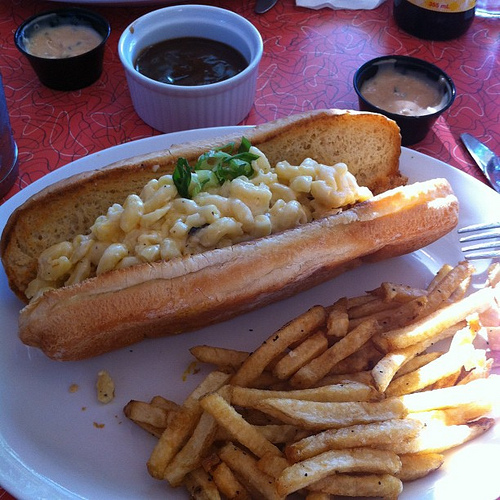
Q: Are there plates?
A: Yes, there is a plate.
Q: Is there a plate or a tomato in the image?
A: Yes, there is a plate.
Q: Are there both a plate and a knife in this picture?
A: Yes, there are both a plate and a knife.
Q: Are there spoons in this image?
A: No, there are no spoons.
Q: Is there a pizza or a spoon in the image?
A: No, there are no spoons or pizzas.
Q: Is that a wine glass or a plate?
A: That is a plate.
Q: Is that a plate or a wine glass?
A: That is a plate.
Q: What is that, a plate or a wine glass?
A: That is a plate.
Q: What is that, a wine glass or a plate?
A: That is a plate.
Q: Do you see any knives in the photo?
A: Yes, there is a knife.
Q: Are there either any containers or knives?
A: Yes, there is a knife.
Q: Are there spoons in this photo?
A: No, there are no spoons.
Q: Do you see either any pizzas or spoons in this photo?
A: No, there are no spoons or pizzas.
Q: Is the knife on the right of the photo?
A: Yes, the knife is on the right of the image.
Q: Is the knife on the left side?
A: No, the knife is on the right of the image.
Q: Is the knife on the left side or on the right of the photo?
A: The knife is on the right of the image.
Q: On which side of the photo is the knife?
A: The knife is on the right of the image.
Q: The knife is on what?
A: The knife is on the table.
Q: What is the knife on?
A: The knife is on the table.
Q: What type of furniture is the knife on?
A: The knife is on the table.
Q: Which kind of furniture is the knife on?
A: The knife is on the table.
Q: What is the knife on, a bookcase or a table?
A: The knife is on a table.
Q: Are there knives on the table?
A: Yes, there is a knife on the table.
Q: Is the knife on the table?
A: Yes, the knife is on the table.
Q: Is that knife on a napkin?
A: No, the knife is on the table.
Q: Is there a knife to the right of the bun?
A: Yes, there is a knife to the right of the bun.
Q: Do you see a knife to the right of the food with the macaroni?
A: Yes, there is a knife to the right of the bun.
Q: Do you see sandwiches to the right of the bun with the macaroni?
A: No, there is a knife to the right of the bun.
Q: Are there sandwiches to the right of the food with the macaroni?
A: No, there is a knife to the right of the bun.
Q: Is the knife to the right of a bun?
A: Yes, the knife is to the right of a bun.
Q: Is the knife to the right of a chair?
A: No, the knife is to the right of a bun.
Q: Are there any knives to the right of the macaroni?
A: Yes, there is a knife to the right of the macaroni.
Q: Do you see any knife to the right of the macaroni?
A: Yes, there is a knife to the right of the macaroni.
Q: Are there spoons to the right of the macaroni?
A: No, there is a knife to the right of the macaroni.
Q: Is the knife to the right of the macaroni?
A: Yes, the knife is to the right of the macaroni.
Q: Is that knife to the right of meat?
A: No, the knife is to the right of the macaroni.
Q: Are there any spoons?
A: No, there are no spoons.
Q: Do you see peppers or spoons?
A: No, there are no spoons or peppers.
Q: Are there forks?
A: Yes, there is a fork.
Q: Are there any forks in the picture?
A: Yes, there is a fork.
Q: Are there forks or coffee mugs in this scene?
A: Yes, there is a fork.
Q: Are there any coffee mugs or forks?
A: Yes, there is a fork.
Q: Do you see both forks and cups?
A: Yes, there are both a fork and a cup.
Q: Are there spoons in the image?
A: No, there are no spoons.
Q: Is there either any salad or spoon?
A: No, there are no spoons or salad.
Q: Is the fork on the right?
A: Yes, the fork is on the right of the image.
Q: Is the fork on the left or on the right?
A: The fork is on the right of the image.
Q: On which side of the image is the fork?
A: The fork is on the right of the image.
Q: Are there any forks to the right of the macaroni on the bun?
A: Yes, there is a fork to the right of the macaroni.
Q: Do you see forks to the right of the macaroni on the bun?
A: Yes, there is a fork to the right of the macaroni.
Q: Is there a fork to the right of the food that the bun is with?
A: Yes, there is a fork to the right of the macaroni.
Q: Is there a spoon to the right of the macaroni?
A: No, there is a fork to the right of the macaroni.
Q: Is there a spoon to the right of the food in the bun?
A: No, there is a fork to the right of the macaroni.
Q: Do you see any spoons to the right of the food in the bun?
A: No, there is a fork to the right of the macaroni.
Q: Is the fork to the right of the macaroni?
A: Yes, the fork is to the right of the macaroni.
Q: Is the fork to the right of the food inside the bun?
A: Yes, the fork is to the right of the macaroni.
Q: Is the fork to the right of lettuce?
A: No, the fork is to the right of the macaroni.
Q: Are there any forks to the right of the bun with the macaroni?
A: Yes, there is a fork to the right of the bun.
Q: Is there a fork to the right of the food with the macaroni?
A: Yes, there is a fork to the right of the bun.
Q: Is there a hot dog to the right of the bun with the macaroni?
A: No, there is a fork to the right of the bun.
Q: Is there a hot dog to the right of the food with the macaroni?
A: No, there is a fork to the right of the bun.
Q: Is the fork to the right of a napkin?
A: No, the fork is to the right of the bun.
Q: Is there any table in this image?
A: Yes, there is a table.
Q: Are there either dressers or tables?
A: Yes, there is a table.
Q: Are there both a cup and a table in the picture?
A: Yes, there are both a table and a cup.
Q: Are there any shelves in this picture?
A: No, there are no shelves.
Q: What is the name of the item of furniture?
A: The piece of furniture is a table.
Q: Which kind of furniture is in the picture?
A: The furniture is a table.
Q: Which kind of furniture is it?
A: The piece of furniture is a table.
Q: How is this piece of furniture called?
A: This is a table.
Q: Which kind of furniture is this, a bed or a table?
A: This is a table.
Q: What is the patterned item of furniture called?
A: The piece of furniture is a table.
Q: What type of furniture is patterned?
A: The furniture is a table.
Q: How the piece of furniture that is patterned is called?
A: The piece of furniture is a table.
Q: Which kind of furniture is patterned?
A: The furniture is a table.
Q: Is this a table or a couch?
A: This is a table.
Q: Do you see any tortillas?
A: No, there are no tortillas.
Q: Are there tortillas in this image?
A: No, there are no tortillas.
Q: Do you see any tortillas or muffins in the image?
A: No, there are no tortillas or muffins.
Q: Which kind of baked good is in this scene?
A: The baked good is a bun.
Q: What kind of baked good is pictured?
A: The baked good is a bun.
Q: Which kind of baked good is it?
A: The food is a bun.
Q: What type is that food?
A: This is a bun.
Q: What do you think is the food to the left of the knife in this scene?
A: The food is a bun.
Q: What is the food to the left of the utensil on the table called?
A: The food is a bun.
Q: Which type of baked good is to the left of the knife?
A: The food is a bun.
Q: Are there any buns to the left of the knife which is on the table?
A: Yes, there is a bun to the left of the knife.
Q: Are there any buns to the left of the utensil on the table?
A: Yes, there is a bun to the left of the knife.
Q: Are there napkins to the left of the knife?
A: No, there is a bun to the left of the knife.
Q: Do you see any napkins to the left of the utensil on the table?
A: No, there is a bun to the left of the knife.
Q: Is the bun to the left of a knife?
A: Yes, the bun is to the left of a knife.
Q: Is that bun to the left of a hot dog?
A: No, the bun is to the left of a knife.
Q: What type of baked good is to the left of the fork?
A: The food is a bun.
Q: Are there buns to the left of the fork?
A: Yes, there is a bun to the left of the fork.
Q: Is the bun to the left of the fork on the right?
A: Yes, the bun is to the left of the fork.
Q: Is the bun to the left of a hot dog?
A: No, the bun is to the left of the fork.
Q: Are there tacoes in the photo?
A: No, there are no tacoes.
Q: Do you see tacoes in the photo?
A: No, there are no tacoes.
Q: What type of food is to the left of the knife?
A: The food is macaroni.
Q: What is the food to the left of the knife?
A: The food is macaroni.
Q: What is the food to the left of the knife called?
A: The food is macaroni.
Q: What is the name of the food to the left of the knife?
A: The food is macaroni.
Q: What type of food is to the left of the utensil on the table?
A: The food is macaroni.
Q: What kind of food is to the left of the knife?
A: The food is macaroni.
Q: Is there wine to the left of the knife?
A: No, there is macaroni to the left of the knife.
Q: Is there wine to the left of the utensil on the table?
A: No, there is macaroni to the left of the knife.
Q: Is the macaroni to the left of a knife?
A: Yes, the macaroni is to the left of a knife.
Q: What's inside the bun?
A: The macaroni is inside the bun.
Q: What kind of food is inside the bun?
A: The food is macaroni.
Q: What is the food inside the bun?
A: The food is macaroni.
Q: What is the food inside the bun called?
A: The food is macaroni.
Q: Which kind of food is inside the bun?
A: The food is macaroni.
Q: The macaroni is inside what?
A: The macaroni is inside the bun.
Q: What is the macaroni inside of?
A: The macaroni is inside the bun.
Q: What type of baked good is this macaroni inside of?
A: The macaroni is inside the bun.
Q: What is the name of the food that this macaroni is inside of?
A: The food is a bun.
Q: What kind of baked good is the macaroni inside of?
A: The macaroni is inside the bun.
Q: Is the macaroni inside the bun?
A: Yes, the macaroni is inside the bun.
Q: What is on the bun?
A: The macaroni is on the bun.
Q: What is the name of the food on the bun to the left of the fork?
A: The food is macaroni.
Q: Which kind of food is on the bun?
A: The food is macaroni.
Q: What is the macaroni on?
A: The macaroni is on the bun.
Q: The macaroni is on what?
A: The macaroni is on the bun.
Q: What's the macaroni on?
A: The macaroni is on the bun.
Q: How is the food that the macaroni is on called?
A: The food is a bun.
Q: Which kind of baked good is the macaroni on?
A: The macaroni is on the bun.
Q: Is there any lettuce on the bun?
A: No, there is macaroni on the bun.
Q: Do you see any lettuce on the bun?
A: No, there is macaroni on the bun.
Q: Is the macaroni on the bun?
A: Yes, the macaroni is on the bun.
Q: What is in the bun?
A: The macaroni is in the bun.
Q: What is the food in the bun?
A: The food is macaroni.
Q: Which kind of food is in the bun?
A: The food is macaroni.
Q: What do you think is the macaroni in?
A: The macaroni is in the bun.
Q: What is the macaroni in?
A: The macaroni is in the bun.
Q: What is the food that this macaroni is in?
A: The food is a bun.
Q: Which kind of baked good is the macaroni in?
A: The macaroni is in the bun.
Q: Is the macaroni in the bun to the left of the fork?
A: Yes, the macaroni is in the bun.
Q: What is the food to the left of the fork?
A: The food is macaroni.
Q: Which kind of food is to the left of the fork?
A: The food is macaroni.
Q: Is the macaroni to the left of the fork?
A: Yes, the macaroni is to the left of the fork.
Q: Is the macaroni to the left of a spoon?
A: No, the macaroni is to the left of the fork.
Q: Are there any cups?
A: Yes, there is a cup.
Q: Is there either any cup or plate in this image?
A: Yes, there is a cup.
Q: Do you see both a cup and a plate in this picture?
A: Yes, there are both a cup and a plate.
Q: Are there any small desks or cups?
A: Yes, there is a small cup.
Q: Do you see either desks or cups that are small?
A: Yes, the cup is small.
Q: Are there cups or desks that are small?
A: Yes, the cup is small.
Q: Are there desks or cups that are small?
A: Yes, the cup is small.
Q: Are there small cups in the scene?
A: Yes, there is a small cup.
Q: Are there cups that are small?
A: Yes, there is a cup that is small.